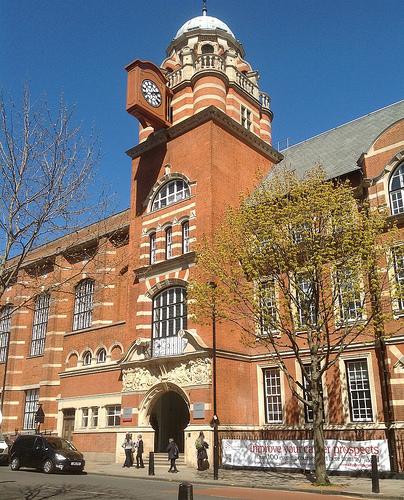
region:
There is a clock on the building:
[122, 62, 169, 122]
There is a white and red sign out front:
[216, 436, 401, 483]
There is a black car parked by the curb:
[9, 431, 84, 484]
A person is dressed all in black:
[159, 436, 186, 471]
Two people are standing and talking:
[118, 428, 150, 470]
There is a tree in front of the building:
[194, 171, 389, 489]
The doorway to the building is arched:
[123, 378, 204, 477]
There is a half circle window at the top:
[143, 172, 192, 213]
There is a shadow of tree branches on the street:
[10, 477, 131, 498]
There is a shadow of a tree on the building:
[234, 366, 393, 492]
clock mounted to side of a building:
[118, 56, 188, 137]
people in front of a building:
[98, 429, 215, 479]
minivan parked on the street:
[8, 427, 90, 481]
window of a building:
[140, 282, 200, 355]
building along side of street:
[12, 9, 397, 492]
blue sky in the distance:
[265, 4, 399, 88]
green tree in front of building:
[182, 158, 402, 485]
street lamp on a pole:
[197, 279, 232, 491]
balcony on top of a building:
[175, 54, 281, 100]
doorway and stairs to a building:
[132, 381, 197, 472]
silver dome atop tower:
[171, 12, 254, 39]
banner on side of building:
[226, 435, 395, 470]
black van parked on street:
[15, 435, 85, 474]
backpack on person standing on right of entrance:
[192, 436, 206, 451]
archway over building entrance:
[135, 390, 190, 421]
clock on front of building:
[125, 70, 168, 121]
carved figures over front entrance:
[120, 353, 210, 392]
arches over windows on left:
[66, 338, 128, 369]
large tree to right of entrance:
[200, 175, 395, 490]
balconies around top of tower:
[169, 55, 274, 105]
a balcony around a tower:
[167, 51, 295, 110]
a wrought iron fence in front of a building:
[215, 427, 402, 473]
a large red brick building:
[0, 23, 402, 477]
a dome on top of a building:
[175, 9, 246, 47]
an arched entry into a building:
[138, 380, 195, 460]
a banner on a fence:
[217, 430, 401, 481]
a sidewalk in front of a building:
[82, 451, 387, 493]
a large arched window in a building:
[136, 277, 196, 352]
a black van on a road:
[7, 423, 89, 473]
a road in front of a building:
[1, 455, 367, 498]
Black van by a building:
[4, 426, 107, 479]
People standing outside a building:
[119, 429, 230, 472]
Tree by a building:
[198, 218, 402, 457]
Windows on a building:
[12, 278, 128, 355]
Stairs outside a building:
[133, 440, 197, 483]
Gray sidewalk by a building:
[103, 447, 191, 497]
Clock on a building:
[120, 62, 177, 124]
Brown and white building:
[113, 57, 287, 344]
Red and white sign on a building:
[212, 435, 401, 486]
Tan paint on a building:
[51, 393, 146, 418]